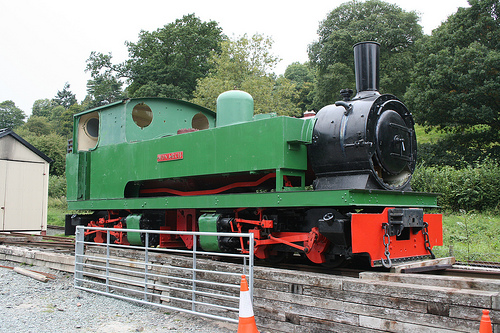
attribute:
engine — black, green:
[85, 90, 347, 218]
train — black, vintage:
[63, 77, 473, 305]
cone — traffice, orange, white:
[226, 270, 265, 324]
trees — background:
[163, 20, 410, 103]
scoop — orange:
[340, 207, 482, 286]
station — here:
[4, 131, 71, 250]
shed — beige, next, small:
[7, 131, 89, 270]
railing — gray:
[94, 236, 167, 278]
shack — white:
[5, 126, 54, 331]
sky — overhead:
[32, 12, 142, 71]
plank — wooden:
[48, 239, 90, 277]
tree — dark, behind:
[420, 26, 481, 131]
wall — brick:
[329, 278, 402, 323]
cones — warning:
[219, 268, 311, 331]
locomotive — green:
[317, 103, 479, 264]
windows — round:
[112, 100, 228, 141]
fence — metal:
[167, 220, 236, 297]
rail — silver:
[172, 219, 261, 243]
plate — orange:
[348, 214, 461, 270]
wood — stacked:
[2, 234, 113, 295]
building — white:
[14, 122, 74, 287]